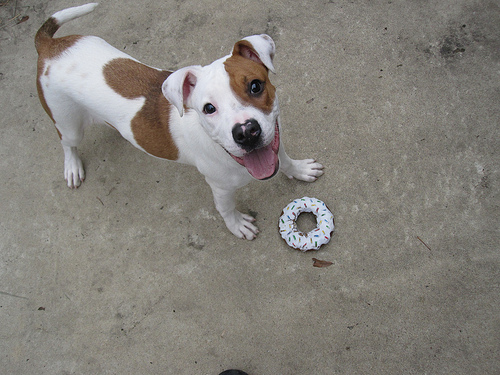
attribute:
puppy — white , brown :
[30, 10, 331, 240]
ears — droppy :
[163, 30, 277, 102]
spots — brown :
[92, 60, 180, 166]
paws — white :
[210, 137, 328, 237]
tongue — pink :
[235, 144, 278, 179]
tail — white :
[27, 3, 107, 35]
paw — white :
[54, 150, 93, 190]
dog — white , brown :
[30, 5, 314, 234]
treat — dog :
[279, 189, 332, 257]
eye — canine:
[243, 70, 273, 103]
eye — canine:
[196, 96, 223, 123]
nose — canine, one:
[232, 114, 261, 147]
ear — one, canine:
[237, 30, 276, 69]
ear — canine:
[164, 60, 194, 110]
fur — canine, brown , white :
[60, 54, 150, 114]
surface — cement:
[128, 260, 271, 340]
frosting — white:
[270, 186, 344, 262]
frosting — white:
[269, 193, 347, 253]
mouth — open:
[207, 109, 344, 200]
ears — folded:
[149, 34, 318, 107]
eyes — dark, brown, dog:
[184, 72, 279, 129]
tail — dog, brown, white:
[30, 6, 113, 52]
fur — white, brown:
[79, 67, 149, 127]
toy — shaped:
[279, 201, 410, 313]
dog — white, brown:
[32, 16, 381, 253]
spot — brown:
[82, 39, 155, 149]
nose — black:
[227, 117, 282, 159]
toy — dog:
[267, 185, 359, 263]